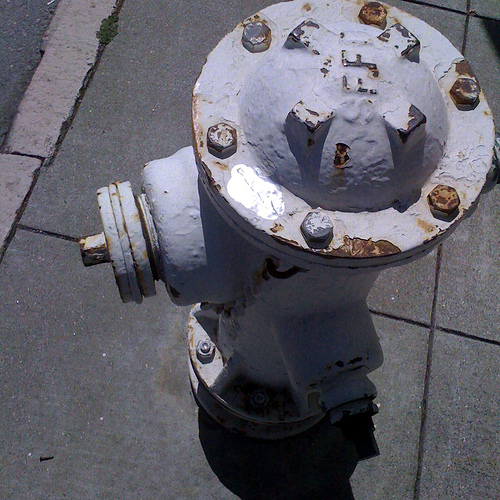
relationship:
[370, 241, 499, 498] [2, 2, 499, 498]
lines on cement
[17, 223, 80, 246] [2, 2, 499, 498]
lines on cement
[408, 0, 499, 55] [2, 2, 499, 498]
lines on cement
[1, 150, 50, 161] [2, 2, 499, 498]
lines on cement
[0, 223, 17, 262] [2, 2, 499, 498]
lines on cement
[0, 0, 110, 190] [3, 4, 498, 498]
curb on edge of sidewalk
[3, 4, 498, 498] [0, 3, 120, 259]
sidewalk has curb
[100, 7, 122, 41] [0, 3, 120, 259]
weeds beside curb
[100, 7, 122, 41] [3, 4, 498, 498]
weeds beside sidewalk